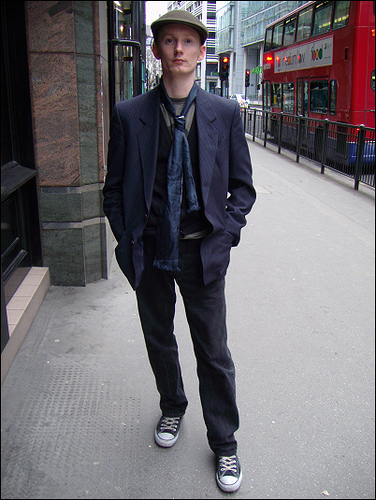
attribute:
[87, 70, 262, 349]
man — black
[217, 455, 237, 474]
shoe laces — white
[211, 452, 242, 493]
sneaker — black, white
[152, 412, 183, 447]
sneaker — black, white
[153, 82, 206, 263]
scarf — blue 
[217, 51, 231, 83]
light — red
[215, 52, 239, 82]
light — red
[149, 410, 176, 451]
shoes — black, white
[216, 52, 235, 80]
traffic lights — red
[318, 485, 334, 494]
spot — white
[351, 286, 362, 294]
spot — white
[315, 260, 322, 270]
spot — white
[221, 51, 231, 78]
light — traffic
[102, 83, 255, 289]
jacket — blue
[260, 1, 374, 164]
bus — red, double decker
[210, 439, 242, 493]
sneaker — black, white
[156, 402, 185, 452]
sneaker — black, white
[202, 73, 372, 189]
railing — metal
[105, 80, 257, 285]
blazer — black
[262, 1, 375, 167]
doubledecker bus — red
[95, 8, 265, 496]
man — posing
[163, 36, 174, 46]
eye — blue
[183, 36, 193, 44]
eye — blue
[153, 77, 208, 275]
scarf — blue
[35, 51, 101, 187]
block — stone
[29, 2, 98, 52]
block — stone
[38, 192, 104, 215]
block — stone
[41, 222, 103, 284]
block — stone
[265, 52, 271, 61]
light — red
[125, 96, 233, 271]
jacket — blue